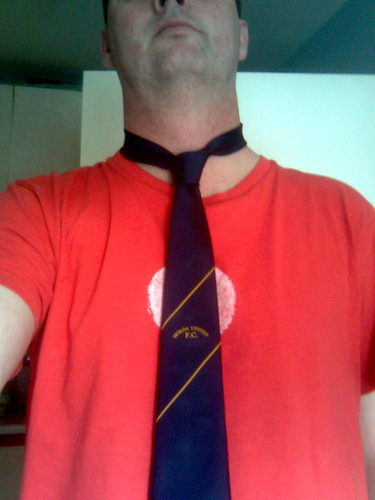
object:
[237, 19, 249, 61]
ear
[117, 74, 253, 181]
neck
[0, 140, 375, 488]
t-shirt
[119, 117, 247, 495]
necktie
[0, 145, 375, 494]
shirt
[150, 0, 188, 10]
nose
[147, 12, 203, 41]
mouth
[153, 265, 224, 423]
stripes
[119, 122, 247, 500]
blue/gold tie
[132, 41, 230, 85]
chin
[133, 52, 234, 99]
beard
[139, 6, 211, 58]
mustache stubble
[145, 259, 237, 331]
white spot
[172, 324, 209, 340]
logo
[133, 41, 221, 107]
hair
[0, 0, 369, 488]
man